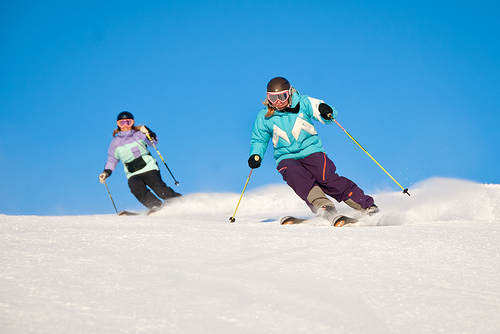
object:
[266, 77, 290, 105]
helmet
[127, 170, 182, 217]
pants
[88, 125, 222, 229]
skier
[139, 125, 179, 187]
pole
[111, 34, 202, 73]
sky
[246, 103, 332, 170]
gloves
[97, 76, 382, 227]
skiers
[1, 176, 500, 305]
snow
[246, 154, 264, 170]
glove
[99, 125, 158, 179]
jacket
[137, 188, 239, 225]
skis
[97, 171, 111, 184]
glove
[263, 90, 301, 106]
goggles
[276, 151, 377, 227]
trousers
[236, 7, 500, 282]
right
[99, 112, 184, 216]
skiier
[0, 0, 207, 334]
left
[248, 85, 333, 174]
jacket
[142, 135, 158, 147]
hand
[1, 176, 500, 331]
hill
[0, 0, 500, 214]
skies